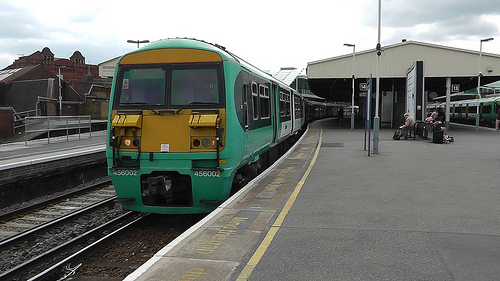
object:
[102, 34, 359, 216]
train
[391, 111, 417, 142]
person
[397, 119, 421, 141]
bench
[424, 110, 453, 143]
person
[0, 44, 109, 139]
building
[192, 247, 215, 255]
letters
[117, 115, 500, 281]
cement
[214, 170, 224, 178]
letters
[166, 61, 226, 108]
windows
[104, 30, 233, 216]
front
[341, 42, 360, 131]
street light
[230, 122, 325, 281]
line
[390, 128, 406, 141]
belongings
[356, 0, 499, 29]
cloud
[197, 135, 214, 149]
head lights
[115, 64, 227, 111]
windshield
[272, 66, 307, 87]
structure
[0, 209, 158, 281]
train tracks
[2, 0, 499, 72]
sky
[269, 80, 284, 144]
door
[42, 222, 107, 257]
part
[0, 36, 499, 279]
train station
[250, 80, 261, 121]
window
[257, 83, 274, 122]
window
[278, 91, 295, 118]
window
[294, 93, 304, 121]
window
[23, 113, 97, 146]
safety rail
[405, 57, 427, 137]
post